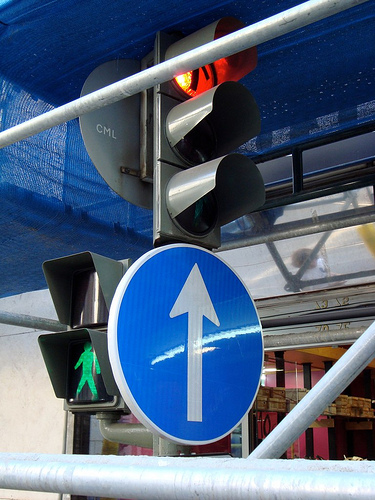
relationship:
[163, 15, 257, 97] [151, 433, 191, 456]
light on pole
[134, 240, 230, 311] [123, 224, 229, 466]
sign on pole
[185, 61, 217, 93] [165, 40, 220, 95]
arrow in light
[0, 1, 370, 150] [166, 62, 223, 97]
bar in front of light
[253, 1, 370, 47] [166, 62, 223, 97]
bar in front of light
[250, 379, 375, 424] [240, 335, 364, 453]
wood inside store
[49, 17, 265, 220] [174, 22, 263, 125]
sign behind red light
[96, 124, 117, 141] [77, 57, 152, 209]
cml on sign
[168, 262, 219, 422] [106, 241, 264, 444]
arrow on sign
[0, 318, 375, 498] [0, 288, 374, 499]
pole on street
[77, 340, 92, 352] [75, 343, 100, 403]
head on green man